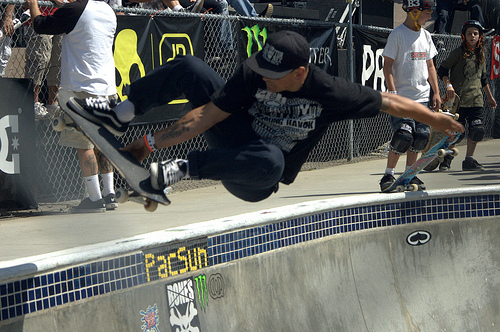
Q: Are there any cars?
A: No, there are no cars.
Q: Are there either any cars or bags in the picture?
A: No, there are no cars or bags.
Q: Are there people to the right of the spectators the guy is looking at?
A: Yes, there is a person to the right of the spectators.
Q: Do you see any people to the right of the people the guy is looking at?
A: Yes, there is a person to the right of the spectators.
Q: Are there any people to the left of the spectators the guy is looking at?
A: No, the person is to the right of the spectators.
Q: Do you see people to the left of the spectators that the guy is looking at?
A: No, the person is to the right of the spectators.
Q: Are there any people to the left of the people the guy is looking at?
A: No, the person is to the right of the spectators.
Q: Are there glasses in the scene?
A: No, there are no glasses.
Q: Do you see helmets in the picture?
A: Yes, there is a helmet.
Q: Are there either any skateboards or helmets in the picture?
A: Yes, there is a helmet.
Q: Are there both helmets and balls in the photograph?
A: No, there is a helmet but no balls.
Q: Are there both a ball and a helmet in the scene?
A: No, there is a helmet but no balls.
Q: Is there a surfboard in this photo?
A: No, there are no surfboards.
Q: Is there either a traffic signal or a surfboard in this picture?
A: No, there are no surfboards or traffic lights.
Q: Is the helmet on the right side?
A: Yes, the helmet is on the right of the image.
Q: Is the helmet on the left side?
A: No, the helmet is on the right of the image.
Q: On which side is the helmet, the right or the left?
A: The helmet is on the right of the image.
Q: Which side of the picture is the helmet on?
A: The helmet is on the right of the image.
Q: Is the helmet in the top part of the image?
A: Yes, the helmet is in the top of the image.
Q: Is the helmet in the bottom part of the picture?
A: No, the helmet is in the top of the image.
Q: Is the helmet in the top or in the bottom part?
A: The helmet is in the top of the image.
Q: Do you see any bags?
A: No, there are no bags.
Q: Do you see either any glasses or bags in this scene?
A: No, there are no bags or glasses.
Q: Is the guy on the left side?
A: Yes, the guy is on the left of the image.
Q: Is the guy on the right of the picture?
A: No, the guy is on the left of the image.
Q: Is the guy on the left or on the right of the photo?
A: The guy is on the left of the image.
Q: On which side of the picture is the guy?
A: The guy is on the left of the image.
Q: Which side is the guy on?
A: The guy is on the left of the image.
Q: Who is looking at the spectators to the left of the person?
A: The guy is looking at the spectators.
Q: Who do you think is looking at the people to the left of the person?
A: The guy is looking at the spectators.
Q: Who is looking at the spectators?
A: The guy is looking at the spectators.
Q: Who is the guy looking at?
A: The guy is looking at the spectators.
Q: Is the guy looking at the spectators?
A: Yes, the guy is looking at the spectators.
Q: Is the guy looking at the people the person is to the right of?
A: Yes, the guy is looking at the spectators.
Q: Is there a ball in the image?
A: No, there are no balls.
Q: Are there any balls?
A: No, there are no balls.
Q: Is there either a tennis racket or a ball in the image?
A: No, there are no balls or rackets.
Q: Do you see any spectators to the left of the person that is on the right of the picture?
A: Yes, there are spectators to the left of the person.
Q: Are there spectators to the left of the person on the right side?
A: Yes, there are spectators to the left of the person.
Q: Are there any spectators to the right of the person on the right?
A: No, the spectators are to the left of the person.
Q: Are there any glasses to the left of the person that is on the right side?
A: No, there are spectators to the left of the person.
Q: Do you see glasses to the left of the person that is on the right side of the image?
A: No, there are spectators to the left of the person.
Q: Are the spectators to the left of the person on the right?
A: Yes, the spectators are to the left of the person.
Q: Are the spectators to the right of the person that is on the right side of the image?
A: No, the spectators are to the left of the person.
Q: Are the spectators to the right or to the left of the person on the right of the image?
A: The spectators are to the left of the person.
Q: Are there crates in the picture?
A: No, there are no crates.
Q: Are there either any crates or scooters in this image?
A: No, there are no crates or scooters.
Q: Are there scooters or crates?
A: No, there are no crates or scooters.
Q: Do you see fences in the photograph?
A: Yes, there is a fence.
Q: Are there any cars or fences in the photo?
A: Yes, there is a fence.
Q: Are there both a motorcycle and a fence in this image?
A: No, there is a fence but no motorcycles.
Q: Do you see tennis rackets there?
A: No, there are no tennis rackets.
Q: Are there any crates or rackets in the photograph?
A: No, there are no rackets or crates.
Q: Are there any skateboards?
A: Yes, there is a skateboard.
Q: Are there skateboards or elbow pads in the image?
A: Yes, there is a skateboard.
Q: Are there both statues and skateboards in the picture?
A: No, there is a skateboard but no statues.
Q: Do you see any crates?
A: No, there are no crates.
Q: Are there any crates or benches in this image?
A: No, there are no crates or benches.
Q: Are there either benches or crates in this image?
A: No, there are no crates or benches.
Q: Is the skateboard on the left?
A: Yes, the skateboard is on the left of the image.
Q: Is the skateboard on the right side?
A: No, the skateboard is on the left of the image.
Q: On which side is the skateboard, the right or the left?
A: The skateboard is on the left of the image.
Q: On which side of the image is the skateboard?
A: The skateboard is on the left of the image.